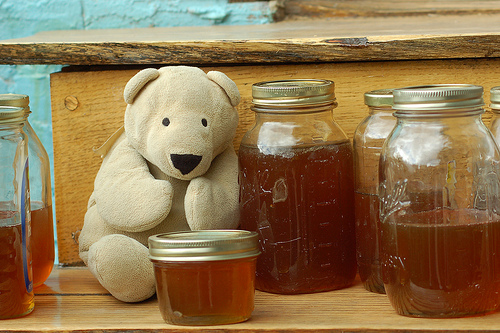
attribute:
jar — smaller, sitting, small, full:
[144, 221, 271, 327]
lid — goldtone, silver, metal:
[144, 227, 262, 258]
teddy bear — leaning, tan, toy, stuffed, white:
[70, 60, 247, 306]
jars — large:
[222, 66, 499, 322]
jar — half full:
[375, 82, 498, 319]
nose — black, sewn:
[168, 150, 202, 177]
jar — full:
[236, 76, 360, 292]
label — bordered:
[16, 154, 35, 299]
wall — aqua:
[3, 2, 278, 36]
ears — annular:
[121, 66, 245, 107]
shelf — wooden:
[2, 265, 499, 333]